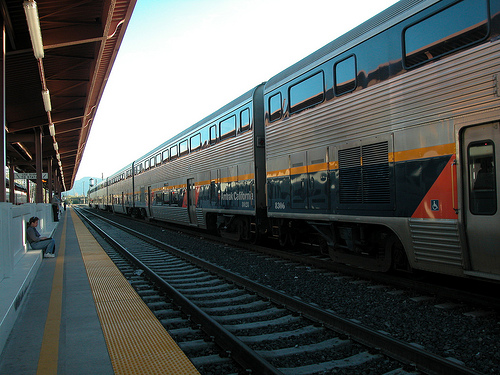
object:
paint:
[35, 206, 206, 375]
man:
[27, 216, 56, 258]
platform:
[0, 201, 201, 375]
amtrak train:
[87, 0, 500, 283]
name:
[220, 191, 254, 201]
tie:
[146, 292, 257, 311]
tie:
[159, 304, 286, 326]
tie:
[165, 312, 304, 337]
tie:
[178, 321, 327, 354]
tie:
[188, 335, 353, 367]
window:
[331, 53, 358, 97]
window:
[286, 69, 324, 116]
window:
[266, 92, 283, 121]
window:
[239, 106, 251, 132]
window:
[218, 114, 237, 140]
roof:
[0, 2, 138, 193]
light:
[42, 89, 52, 113]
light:
[48, 124, 55, 138]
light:
[56, 153, 61, 161]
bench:
[0, 200, 65, 350]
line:
[67, 202, 202, 375]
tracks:
[71, 202, 500, 375]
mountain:
[74, 176, 107, 197]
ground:
[0, 202, 500, 375]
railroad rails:
[72, 200, 500, 374]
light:
[17, 0, 46, 61]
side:
[73, 0, 500, 285]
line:
[35, 206, 68, 375]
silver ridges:
[341, 38, 500, 144]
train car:
[262, 0, 500, 283]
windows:
[134, 132, 201, 176]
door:
[457, 119, 500, 276]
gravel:
[69, 204, 499, 375]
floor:
[0, 201, 500, 375]